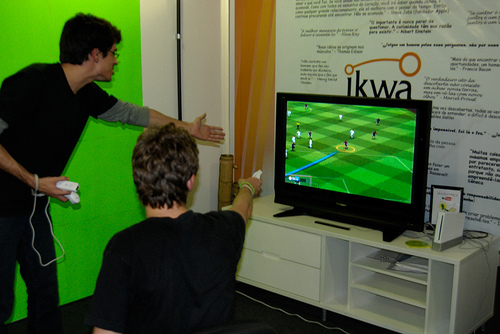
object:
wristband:
[239, 181, 256, 194]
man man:
[1, 10, 264, 334]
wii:
[433, 209, 465, 246]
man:
[91, 122, 260, 334]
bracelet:
[239, 182, 256, 195]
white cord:
[236, 289, 349, 334]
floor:
[12, 282, 375, 333]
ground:
[432, 132, 444, 158]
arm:
[93, 87, 187, 136]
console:
[431, 212, 466, 252]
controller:
[55, 179, 80, 204]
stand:
[216, 190, 499, 333]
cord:
[175, 0, 182, 120]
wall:
[273, 2, 498, 244]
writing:
[274, 0, 499, 234]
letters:
[348, 70, 413, 100]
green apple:
[56, 180, 81, 205]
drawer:
[242, 215, 322, 267]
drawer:
[237, 246, 323, 303]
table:
[216, 192, 497, 332]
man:
[0, 11, 226, 333]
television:
[272, 91, 434, 242]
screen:
[284, 100, 416, 205]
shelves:
[346, 246, 432, 333]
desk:
[224, 194, 500, 334]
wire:
[29, 174, 66, 267]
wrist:
[32, 174, 42, 189]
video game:
[283, 99, 417, 205]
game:
[50, 174, 86, 208]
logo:
[343, 52, 423, 101]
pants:
[2, 194, 72, 333]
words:
[284, 0, 500, 109]